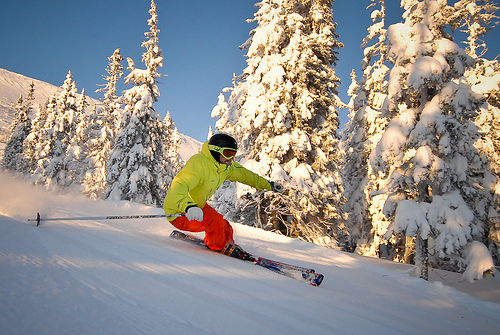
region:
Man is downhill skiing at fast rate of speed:
[1, 124, 328, 293]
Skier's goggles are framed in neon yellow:
[202, 137, 246, 163]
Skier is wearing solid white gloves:
[185, 207, 211, 222]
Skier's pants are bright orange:
[166, 200, 255, 253]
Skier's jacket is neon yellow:
[156, 143, 313, 223]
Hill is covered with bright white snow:
[33, 228, 278, 330]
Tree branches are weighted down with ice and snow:
[387, 49, 472, 289]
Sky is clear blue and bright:
[8, 2, 229, 92]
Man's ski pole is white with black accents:
[13, 206, 166, 231]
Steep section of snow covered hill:
[0, 60, 87, 168]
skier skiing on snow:
[24, 118, 343, 299]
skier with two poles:
[22, 174, 305, 233]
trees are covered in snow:
[5, 0, 499, 296]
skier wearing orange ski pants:
[162, 189, 246, 264]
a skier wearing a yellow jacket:
[142, 132, 289, 233]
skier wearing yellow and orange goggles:
[198, 125, 241, 179]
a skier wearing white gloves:
[172, 172, 289, 226]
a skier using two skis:
[154, 210, 338, 299]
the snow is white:
[0, 0, 499, 333]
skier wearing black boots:
[201, 227, 252, 263]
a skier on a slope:
[31, 85, 493, 312]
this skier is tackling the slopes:
[18, 109, 363, 322]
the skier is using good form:
[12, 94, 398, 308]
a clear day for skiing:
[5, 9, 488, 255]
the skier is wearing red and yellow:
[148, 122, 293, 302]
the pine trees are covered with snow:
[15, 33, 375, 248]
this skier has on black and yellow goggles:
[169, 115, 266, 191]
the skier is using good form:
[135, 188, 379, 300]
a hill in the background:
[5, 48, 230, 255]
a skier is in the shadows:
[35, 100, 412, 334]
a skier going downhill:
[31, 129, 326, 286]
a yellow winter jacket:
[157, 139, 272, 225]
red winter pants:
[170, 200, 234, 254]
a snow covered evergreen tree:
[103, 0, 168, 199]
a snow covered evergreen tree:
[80, 42, 129, 193]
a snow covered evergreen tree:
[39, 80, 94, 190]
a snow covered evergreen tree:
[0, 79, 35, 174]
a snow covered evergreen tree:
[220, 2, 345, 247]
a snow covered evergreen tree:
[373, 2, 473, 277]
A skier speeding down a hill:
[25, 122, 340, 291]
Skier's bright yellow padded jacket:
[159, 143, 274, 223]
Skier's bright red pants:
[160, 197, 244, 252]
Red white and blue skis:
[157, 227, 329, 292]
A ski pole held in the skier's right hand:
[25, 206, 200, 229]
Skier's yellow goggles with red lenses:
[200, 140, 239, 162]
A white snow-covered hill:
[1, 62, 498, 333]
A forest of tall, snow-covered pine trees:
[10, 1, 494, 287]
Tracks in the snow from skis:
[15, 206, 290, 333]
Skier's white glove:
[180, 207, 206, 223]